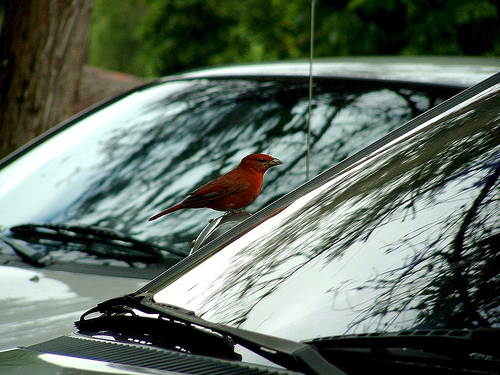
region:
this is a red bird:
[149, 153, 286, 224]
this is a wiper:
[102, 275, 312, 371]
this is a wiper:
[9, 216, 167, 264]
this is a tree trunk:
[12, 4, 85, 135]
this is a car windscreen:
[3, 84, 418, 279]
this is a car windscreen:
[148, 82, 486, 373]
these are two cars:
[2, 71, 497, 366]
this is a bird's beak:
[273, 157, 285, 168]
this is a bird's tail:
[148, 190, 193, 227]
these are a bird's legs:
[226, 207, 253, 216]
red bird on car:
[160, 152, 283, 231]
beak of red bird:
[269, 155, 281, 167]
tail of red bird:
[149, 195, 199, 222]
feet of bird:
[235, 213, 249, 221]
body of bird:
[200, 182, 249, 206]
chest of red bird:
[246, 178, 268, 197]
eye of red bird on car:
[255, 154, 265, 164]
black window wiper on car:
[106, 291, 343, 373]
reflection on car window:
[218, 130, 498, 367]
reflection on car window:
[31, 75, 425, 258]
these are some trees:
[168, 0, 275, 65]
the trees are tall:
[145, 5, 236, 55]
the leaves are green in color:
[187, 5, 257, 50]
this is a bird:
[146, 140, 286, 220]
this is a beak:
[268, 155, 285, 170]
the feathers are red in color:
[237, 177, 259, 198]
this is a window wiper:
[20, 217, 177, 254]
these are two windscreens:
[94, 79, 496, 337]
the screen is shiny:
[302, 222, 404, 304]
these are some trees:
[97, 10, 343, 42]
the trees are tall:
[237, 3, 304, 59]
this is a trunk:
[8, 15, 82, 89]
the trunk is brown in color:
[13, 17, 48, 67]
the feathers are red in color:
[243, 184, 258, 191]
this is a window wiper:
[95, 289, 351, 373]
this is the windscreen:
[126, 104, 181, 180]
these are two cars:
[28, 54, 488, 344]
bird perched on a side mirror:
[139, 141, 293, 238]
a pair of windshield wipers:
[76, 266, 495, 373]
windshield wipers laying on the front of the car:
[9, 213, 175, 265]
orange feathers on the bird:
[142, 145, 299, 232]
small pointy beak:
[270, 155, 287, 167]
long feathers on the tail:
[138, 190, 192, 235]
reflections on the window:
[202, 88, 497, 345]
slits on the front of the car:
[29, 321, 287, 373]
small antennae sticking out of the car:
[299, 0, 323, 182]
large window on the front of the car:
[0, 50, 455, 262]